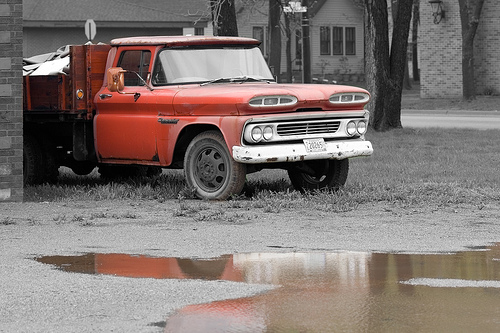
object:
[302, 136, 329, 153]
license plate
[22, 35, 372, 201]
truck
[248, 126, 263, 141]
headlights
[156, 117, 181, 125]
logo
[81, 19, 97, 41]
street sign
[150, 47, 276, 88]
windshield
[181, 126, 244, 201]
front tire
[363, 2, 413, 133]
tree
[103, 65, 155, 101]
mirror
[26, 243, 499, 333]
water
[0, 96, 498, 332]
ground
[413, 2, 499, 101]
building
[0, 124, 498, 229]
grass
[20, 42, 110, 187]
truck bed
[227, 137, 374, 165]
bumper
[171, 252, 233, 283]
truck reflection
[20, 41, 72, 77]
cargo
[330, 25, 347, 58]
window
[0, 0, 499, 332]
background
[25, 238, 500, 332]
puddle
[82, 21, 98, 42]
back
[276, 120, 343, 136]
grill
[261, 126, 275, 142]
light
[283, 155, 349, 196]
wheel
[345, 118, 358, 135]
light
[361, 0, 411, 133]
stem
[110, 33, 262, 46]
bonnet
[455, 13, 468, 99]
edge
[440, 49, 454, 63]
part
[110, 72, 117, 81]
part